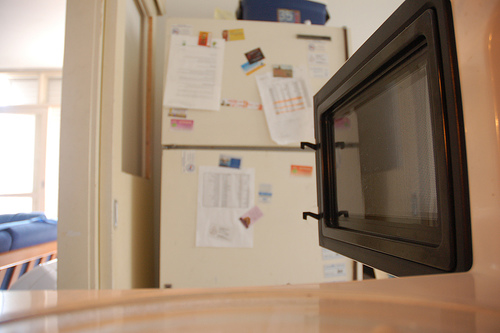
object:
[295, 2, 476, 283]
door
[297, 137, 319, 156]
hook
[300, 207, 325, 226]
hook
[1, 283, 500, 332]
dish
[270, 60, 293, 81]
magnets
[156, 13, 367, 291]
fridge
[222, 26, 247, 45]
magnets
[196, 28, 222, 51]
magnets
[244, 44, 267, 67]
magnets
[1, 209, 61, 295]
couch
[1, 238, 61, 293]
frame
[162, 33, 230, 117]
paper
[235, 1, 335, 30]
tub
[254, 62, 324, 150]
paper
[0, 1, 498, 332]
kitchen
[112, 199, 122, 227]
switch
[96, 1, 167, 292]
wall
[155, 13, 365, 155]
freezer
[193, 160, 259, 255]
paper